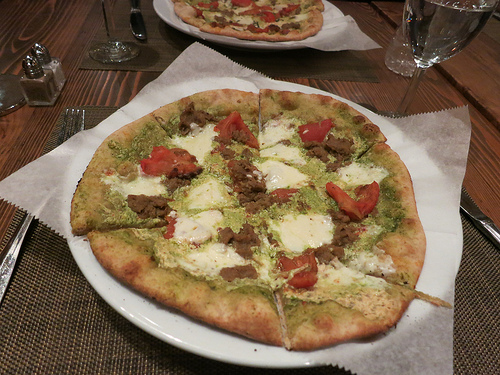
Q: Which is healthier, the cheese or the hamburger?
A: The cheese is healthier than the hamburger.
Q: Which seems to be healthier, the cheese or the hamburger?
A: The cheese is healthier than the hamburger.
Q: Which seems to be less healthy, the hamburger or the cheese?
A: The hamburger is less healthy than the cheese.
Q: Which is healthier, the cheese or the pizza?
A: The cheese is healthier than the pizza.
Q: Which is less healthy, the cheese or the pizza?
A: The pizza is less healthy than the cheese.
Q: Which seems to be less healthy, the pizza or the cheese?
A: The pizza is less healthy than the cheese.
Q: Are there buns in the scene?
A: No, there are no buns.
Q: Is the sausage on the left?
A: Yes, the sausage is on the left of the image.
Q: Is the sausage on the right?
A: No, the sausage is on the left of the image.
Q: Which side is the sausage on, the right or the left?
A: The sausage is on the left of the image.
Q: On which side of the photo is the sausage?
A: The sausage is on the left of the image.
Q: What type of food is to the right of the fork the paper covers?
A: The food is a sausage.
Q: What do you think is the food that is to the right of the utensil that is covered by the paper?
A: The food is a sausage.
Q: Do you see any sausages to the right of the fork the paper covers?
A: Yes, there is a sausage to the right of the fork.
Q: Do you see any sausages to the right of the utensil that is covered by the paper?
A: Yes, there is a sausage to the right of the fork.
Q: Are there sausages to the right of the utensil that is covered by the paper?
A: Yes, there is a sausage to the right of the fork.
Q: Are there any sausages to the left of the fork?
A: No, the sausage is to the right of the fork.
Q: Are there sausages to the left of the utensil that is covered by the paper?
A: No, the sausage is to the right of the fork.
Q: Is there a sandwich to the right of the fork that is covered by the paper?
A: No, there is a sausage to the right of the fork.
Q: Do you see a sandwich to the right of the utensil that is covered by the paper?
A: No, there is a sausage to the right of the fork.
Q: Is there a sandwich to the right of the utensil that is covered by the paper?
A: No, there is a sausage to the right of the fork.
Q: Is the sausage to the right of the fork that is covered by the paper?
A: Yes, the sausage is to the right of the fork.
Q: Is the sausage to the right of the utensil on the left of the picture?
A: Yes, the sausage is to the right of the fork.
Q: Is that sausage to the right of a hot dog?
A: No, the sausage is to the right of the fork.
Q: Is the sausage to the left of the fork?
A: No, the sausage is to the right of the fork.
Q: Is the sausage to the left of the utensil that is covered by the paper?
A: No, the sausage is to the right of the fork.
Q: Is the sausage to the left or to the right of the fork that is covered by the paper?
A: The sausage is to the right of the fork.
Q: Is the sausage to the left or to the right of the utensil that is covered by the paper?
A: The sausage is to the right of the fork.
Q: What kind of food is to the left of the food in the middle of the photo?
A: The food is a sausage.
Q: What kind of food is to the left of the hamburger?
A: The food is a sausage.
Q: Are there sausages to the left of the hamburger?
A: Yes, there is a sausage to the left of the hamburger.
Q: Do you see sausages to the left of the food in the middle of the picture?
A: Yes, there is a sausage to the left of the hamburger.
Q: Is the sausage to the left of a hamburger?
A: Yes, the sausage is to the left of a hamburger.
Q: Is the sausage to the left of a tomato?
A: No, the sausage is to the left of a hamburger.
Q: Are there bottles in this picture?
A: Yes, there is a bottle.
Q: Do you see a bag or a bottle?
A: Yes, there is a bottle.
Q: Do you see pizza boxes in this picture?
A: No, there are no pizza boxes.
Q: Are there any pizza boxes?
A: No, there are no pizza boxes.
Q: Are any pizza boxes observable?
A: No, there are no pizza boxes.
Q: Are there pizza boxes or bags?
A: No, there are no pizza boxes or bags.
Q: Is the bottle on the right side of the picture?
A: Yes, the bottle is on the right of the image.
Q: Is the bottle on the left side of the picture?
A: No, the bottle is on the right of the image.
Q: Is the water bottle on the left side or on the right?
A: The bottle is on the right of the image.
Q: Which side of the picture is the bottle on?
A: The bottle is on the right of the image.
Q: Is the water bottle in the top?
A: Yes, the bottle is in the top of the image.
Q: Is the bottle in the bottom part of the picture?
A: No, the bottle is in the top of the image.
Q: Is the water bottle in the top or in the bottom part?
A: The bottle is in the top of the image.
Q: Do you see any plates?
A: Yes, there is a plate.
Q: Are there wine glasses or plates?
A: Yes, there is a plate.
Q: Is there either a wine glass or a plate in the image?
A: Yes, there is a plate.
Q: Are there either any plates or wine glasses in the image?
A: Yes, there is a plate.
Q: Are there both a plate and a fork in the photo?
A: Yes, there are both a plate and a fork.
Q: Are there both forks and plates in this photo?
A: Yes, there are both a plate and a fork.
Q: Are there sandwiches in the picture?
A: No, there are no sandwiches.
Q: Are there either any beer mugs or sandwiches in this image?
A: No, there are no sandwiches or beer mugs.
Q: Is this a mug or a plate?
A: This is a plate.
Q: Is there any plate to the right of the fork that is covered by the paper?
A: Yes, there is a plate to the right of the fork.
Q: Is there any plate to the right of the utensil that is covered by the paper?
A: Yes, there is a plate to the right of the fork.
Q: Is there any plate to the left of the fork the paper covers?
A: No, the plate is to the right of the fork.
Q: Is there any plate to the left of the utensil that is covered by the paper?
A: No, the plate is to the right of the fork.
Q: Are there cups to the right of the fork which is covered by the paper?
A: No, there is a plate to the right of the fork.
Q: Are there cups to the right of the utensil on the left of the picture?
A: No, there is a plate to the right of the fork.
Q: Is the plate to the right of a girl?
A: No, the plate is to the right of a fork.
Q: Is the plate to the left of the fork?
A: No, the plate is to the right of the fork.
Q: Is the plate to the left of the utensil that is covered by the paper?
A: No, the plate is to the right of the fork.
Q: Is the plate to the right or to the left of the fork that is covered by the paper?
A: The plate is to the right of the fork.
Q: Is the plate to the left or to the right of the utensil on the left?
A: The plate is to the right of the fork.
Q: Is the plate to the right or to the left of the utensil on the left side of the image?
A: The plate is to the right of the fork.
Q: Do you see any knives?
A: Yes, there is a knife.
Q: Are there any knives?
A: Yes, there is a knife.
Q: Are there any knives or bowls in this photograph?
A: Yes, there is a knife.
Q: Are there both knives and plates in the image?
A: Yes, there are both a knife and a plate.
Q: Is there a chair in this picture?
A: No, there are no chairs.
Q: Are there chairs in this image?
A: No, there are no chairs.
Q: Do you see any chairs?
A: No, there are no chairs.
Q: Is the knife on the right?
A: Yes, the knife is on the right of the image.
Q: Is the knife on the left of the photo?
A: No, the knife is on the right of the image.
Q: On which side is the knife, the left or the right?
A: The knife is on the right of the image.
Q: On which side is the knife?
A: The knife is on the right of the image.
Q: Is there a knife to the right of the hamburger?
A: Yes, there is a knife to the right of the hamburger.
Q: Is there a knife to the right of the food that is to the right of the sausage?
A: Yes, there is a knife to the right of the hamburger.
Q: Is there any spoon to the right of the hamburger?
A: No, there is a knife to the right of the hamburger.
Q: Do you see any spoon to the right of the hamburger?
A: No, there is a knife to the right of the hamburger.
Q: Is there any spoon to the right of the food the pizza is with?
A: No, there is a knife to the right of the hamburger.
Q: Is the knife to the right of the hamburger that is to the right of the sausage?
A: Yes, the knife is to the right of the hamburger.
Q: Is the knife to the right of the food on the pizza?
A: Yes, the knife is to the right of the hamburger.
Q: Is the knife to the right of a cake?
A: No, the knife is to the right of the hamburger.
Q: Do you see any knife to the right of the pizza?
A: Yes, there is a knife to the right of the pizza.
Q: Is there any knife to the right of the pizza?
A: Yes, there is a knife to the right of the pizza.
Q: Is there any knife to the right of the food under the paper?
A: Yes, there is a knife to the right of the pizza.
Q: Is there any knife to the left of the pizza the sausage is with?
A: No, the knife is to the right of the pizza.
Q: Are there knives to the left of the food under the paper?
A: No, the knife is to the right of the pizza.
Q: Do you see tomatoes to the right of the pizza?
A: No, there is a knife to the right of the pizza.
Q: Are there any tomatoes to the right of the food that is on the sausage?
A: No, there is a knife to the right of the pizza.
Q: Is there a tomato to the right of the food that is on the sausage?
A: No, there is a knife to the right of the pizza.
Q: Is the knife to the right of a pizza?
A: Yes, the knife is to the right of a pizza.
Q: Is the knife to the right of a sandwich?
A: No, the knife is to the right of a pizza.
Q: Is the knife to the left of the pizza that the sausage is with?
A: No, the knife is to the right of the pizza.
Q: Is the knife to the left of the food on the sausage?
A: No, the knife is to the right of the pizza.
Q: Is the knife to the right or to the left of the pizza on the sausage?
A: The knife is to the right of the pizza.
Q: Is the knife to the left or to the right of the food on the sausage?
A: The knife is to the right of the pizza.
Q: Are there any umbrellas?
A: No, there are no umbrellas.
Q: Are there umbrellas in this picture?
A: No, there are no umbrellas.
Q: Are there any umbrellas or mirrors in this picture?
A: No, there are no umbrellas or mirrors.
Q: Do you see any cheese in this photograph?
A: Yes, there is cheese.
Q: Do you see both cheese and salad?
A: No, there is cheese but no salad.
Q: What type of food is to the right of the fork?
A: The food is cheese.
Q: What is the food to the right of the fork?
A: The food is cheese.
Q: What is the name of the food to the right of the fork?
A: The food is cheese.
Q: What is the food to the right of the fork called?
A: The food is cheese.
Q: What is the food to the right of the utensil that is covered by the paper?
A: The food is cheese.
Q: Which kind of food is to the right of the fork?
A: The food is cheese.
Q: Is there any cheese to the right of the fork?
A: Yes, there is cheese to the right of the fork.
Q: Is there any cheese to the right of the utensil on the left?
A: Yes, there is cheese to the right of the fork.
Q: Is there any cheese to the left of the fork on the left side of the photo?
A: No, the cheese is to the right of the fork.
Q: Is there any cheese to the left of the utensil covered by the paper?
A: No, the cheese is to the right of the fork.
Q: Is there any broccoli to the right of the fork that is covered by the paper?
A: No, there is cheese to the right of the fork.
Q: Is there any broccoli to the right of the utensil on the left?
A: No, there is cheese to the right of the fork.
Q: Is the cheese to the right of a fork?
A: Yes, the cheese is to the right of a fork.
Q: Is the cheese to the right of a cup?
A: No, the cheese is to the right of a fork.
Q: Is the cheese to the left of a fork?
A: No, the cheese is to the right of a fork.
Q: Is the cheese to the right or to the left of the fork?
A: The cheese is to the right of the fork.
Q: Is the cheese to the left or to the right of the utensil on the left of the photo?
A: The cheese is to the right of the fork.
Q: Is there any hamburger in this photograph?
A: Yes, there is a hamburger.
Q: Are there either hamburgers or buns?
A: Yes, there is a hamburger.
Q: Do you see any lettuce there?
A: No, there is no lettuce.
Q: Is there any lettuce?
A: No, there is no lettuce.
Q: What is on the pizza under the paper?
A: The hamburger is on the pizza.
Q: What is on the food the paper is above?
A: The hamburger is on the pizza.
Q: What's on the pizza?
A: The hamburger is on the pizza.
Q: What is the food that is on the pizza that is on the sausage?
A: The food is a hamburger.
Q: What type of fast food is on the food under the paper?
A: The food is a hamburger.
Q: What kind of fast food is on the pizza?
A: The food is a hamburger.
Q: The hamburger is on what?
A: The hamburger is on the pizza.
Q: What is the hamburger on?
A: The hamburger is on the pizza.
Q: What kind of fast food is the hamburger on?
A: The hamburger is on the pizza.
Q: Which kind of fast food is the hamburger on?
A: The hamburger is on the pizza.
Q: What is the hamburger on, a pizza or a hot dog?
A: The hamburger is on a pizza.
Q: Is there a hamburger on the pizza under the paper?
A: Yes, there is a hamburger on the pizza.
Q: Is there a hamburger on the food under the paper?
A: Yes, there is a hamburger on the pizza.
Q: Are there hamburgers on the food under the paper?
A: Yes, there is a hamburger on the pizza.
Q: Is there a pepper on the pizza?
A: No, there is a hamburger on the pizza.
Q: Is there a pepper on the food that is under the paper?
A: No, there is a hamburger on the pizza.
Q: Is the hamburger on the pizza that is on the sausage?
A: Yes, the hamburger is on the pizza.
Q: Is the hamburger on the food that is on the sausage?
A: Yes, the hamburger is on the pizza.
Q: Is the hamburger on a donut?
A: No, the hamburger is on the pizza.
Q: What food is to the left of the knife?
A: The food is a hamburger.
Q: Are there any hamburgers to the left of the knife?
A: Yes, there is a hamburger to the left of the knife.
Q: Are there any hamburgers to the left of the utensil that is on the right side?
A: Yes, there is a hamburger to the left of the knife.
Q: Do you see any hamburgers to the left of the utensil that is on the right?
A: Yes, there is a hamburger to the left of the knife.